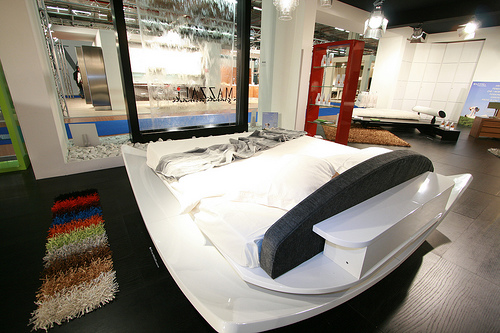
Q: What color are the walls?
A: White.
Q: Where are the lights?
A: Ceiling.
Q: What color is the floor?
A: Gray.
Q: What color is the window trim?
A: Black.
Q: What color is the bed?
A: White.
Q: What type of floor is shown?
A: Hardwood.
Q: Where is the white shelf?
A: Above the headboard.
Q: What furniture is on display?
A: Bed.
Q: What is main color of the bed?
A: White.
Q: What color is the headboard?
A: Black.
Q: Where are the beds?
A: Store.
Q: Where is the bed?
A: In front of a window.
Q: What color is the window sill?
A: Black.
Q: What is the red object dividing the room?
A: Knick knack shelf.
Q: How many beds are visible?
A: 2.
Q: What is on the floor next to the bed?
A: Multi colored rug.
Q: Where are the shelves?
A: Attached to the headboard.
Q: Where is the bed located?
A: On wood plank floor.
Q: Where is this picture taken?
A: A bedroom.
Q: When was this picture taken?
A: Daytime.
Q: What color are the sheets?
A: White.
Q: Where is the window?
A: The end of the bed.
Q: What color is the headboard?
A: Black.